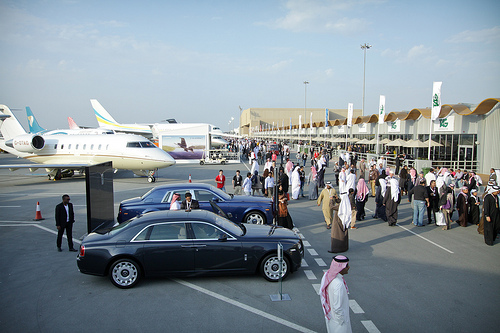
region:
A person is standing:
[326, 187, 361, 244]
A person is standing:
[315, 232, 355, 327]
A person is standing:
[54, 192, 78, 248]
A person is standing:
[378, 171, 403, 227]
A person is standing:
[411, 173, 430, 226]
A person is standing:
[477, 177, 499, 243]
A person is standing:
[456, 182, 470, 219]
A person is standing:
[466, 187, 480, 225]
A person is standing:
[307, 163, 319, 198]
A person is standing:
[288, 157, 308, 199]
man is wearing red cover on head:
[307, 248, 368, 327]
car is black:
[68, 216, 364, 297]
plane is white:
[0, 126, 176, 225]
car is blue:
[123, 174, 289, 222]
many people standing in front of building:
[218, 127, 495, 242]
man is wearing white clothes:
[296, 240, 366, 327]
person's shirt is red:
[203, 168, 230, 195]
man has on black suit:
[38, 179, 97, 302]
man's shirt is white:
[53, 192, 80, 242]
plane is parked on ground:
[7, 89, 224, 201]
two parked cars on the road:
[108, 172, 289, 308]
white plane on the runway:
[10, 89, 183, 189]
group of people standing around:
[283, 135, 440, 235]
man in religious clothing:
[303, 246, 370, 320]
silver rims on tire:
[102, 256, 152, 289]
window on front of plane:
[121, 129, 175, 161]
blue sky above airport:
[168, 59, 253, 101]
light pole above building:
[348, 39, 388, 83]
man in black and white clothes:
[38, 186, 83, 245]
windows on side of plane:
[41, 136, 125, 161]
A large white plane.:
[13, 118, 160, 146]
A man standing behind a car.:
[52, 192, 96, 245]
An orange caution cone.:
[27, 201, 48, 235]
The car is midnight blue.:
[212, 246, 236, 267]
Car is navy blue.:
[137, 190, 155, 214]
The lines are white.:
[231, 299, 270, 317]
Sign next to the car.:
[266, 241, 296, 276]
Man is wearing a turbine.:
[307, 254, 375, 310]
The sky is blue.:
[162, 37, 232, 65]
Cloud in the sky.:
[262, 0, 375, 55]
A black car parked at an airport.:
[69, 214, 300, 294]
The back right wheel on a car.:
[104, 261, 153, 291]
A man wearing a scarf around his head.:
[318, 216, 381, 331]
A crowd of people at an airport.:
[201, 143, 496, 331]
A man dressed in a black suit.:
[39, 194, 84, 261]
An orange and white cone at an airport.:
[27, 200, 48, 230]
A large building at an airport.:
[236, 105, 355, 122]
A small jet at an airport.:
[0, 94, 190, 181]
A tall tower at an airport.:
[351, 37, 385, 119]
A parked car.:
[103, 156, 294, 230]